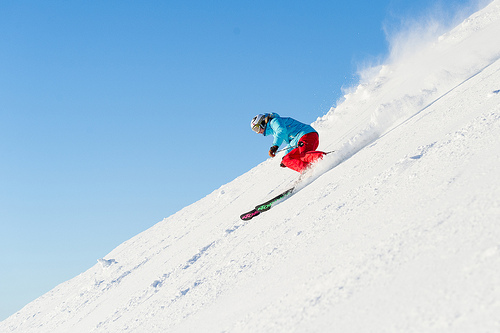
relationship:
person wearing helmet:
[247, 110, 327, 173] [249, 111, 269, 132]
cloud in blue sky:
[0, 0, 492, 320] [2, 3, 228, 177]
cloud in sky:
[0, 0, 492, 320] [44, 113, 128, 167]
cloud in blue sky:
[0, 0, 492, 320] [0, 0, 492, 319]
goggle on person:
[253, 122, 262, 130] [247, 110, 327, 173]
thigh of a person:
[299, 139, 314, 154] [247, 110, 327, 173]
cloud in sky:
[0, 127, 144, 317] [1, 4, 206, 195]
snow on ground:
[361, 114, 433, 161] [0, 1, 498, 331]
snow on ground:
[0, 0, 499, 332] [0, 1, 498, 331]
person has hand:
[247, 110, 327, 173] [265, 145, 281, 154]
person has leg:
[247, 110, 327, 173] [282, 146, 309, 184]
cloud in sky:
[0, 0, 492, 320] [258, 32, 348, 66]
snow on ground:
[0, 0, 499, 332] [142, 117, 430, 277]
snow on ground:
[0, 0, 499, 332] [362, 103, 441, 192]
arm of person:
[271, 119, 286, 150] [250, 110, 332, 182]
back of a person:
[262, 116, 322, 142] [249, 113, 329, 168]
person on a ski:
[247, 110, 327, 173] [238, 179, 313, 222]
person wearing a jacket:
[247, 110, 336, 174] [262, 111, 317, 153]